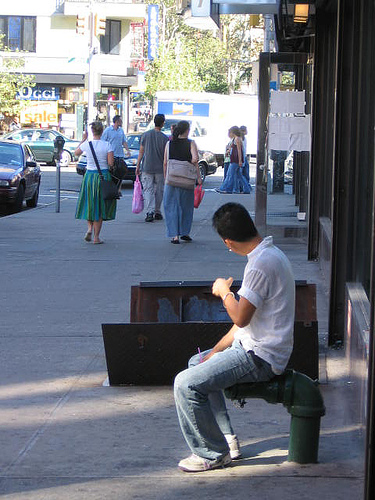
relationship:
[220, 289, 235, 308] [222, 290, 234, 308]
bracelet on bracelet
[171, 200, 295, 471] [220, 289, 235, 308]
man has bracelet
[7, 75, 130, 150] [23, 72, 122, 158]
storefront has sing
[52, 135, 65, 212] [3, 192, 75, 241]
parking meter near curb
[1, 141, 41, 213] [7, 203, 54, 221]
car near curb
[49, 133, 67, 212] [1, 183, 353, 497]
parking meter in sidewalk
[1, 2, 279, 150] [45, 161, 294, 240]
buildings by street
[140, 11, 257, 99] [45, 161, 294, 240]
trees by street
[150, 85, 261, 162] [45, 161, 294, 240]
truck by street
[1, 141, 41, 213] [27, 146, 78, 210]
car on street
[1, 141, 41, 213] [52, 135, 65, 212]
car parked by parking meter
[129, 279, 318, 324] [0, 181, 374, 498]
door in pavement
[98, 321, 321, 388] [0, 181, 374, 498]
door in pavement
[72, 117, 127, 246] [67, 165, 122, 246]
lady wearing green skirt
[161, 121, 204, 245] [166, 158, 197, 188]
lady carrying beige bag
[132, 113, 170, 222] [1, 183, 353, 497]
pedestrians on sidewalk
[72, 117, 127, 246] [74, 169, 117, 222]
lady wearing green skirt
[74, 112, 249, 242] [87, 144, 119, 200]
pedestrians with bag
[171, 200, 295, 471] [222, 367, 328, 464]
man on fire hydrant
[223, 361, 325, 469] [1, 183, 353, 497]
fire hydrant on sidewalk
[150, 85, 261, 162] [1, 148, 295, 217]
truck on road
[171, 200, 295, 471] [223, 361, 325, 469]
man on fire hydrant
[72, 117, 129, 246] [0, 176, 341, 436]
lady on sidewalk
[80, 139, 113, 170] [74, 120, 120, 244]
shirt on lady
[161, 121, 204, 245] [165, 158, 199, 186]
lady holding beige bag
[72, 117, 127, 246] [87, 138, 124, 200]
lady holding bag